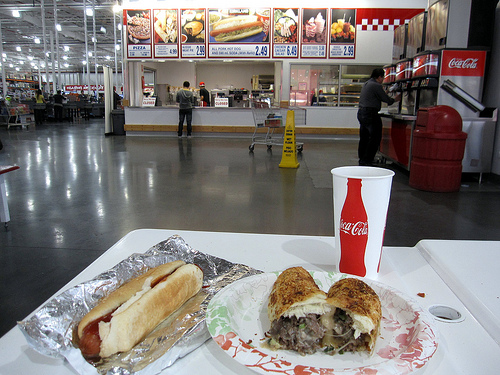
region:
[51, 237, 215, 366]
hot dog in tin foil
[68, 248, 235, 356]
hot dog with ketchup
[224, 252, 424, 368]
round plate with food on it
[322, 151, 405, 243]
cup next to plate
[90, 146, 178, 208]
floor next to the table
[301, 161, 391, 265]
white cup with red bottle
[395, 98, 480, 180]
red trash can on floor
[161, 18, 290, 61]
menu of food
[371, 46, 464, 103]
coke machine next to man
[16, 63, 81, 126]
people in the store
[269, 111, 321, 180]
the cone is yellow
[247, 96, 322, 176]
buggy behind the cone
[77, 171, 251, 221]
the floor is gray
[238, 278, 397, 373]
sandwich on the plate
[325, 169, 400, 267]
cup behind the plate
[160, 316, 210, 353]
the foil is aluminum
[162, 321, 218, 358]
the foil is silver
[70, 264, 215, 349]
hot dog in bun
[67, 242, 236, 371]
hot dog on foil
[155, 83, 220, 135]
man at the counter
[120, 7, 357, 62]
menu on wall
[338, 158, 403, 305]
paper cup is red and white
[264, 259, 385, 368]
meat inside two pieces of bread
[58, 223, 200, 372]
hot dog on aluminum foil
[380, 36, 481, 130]
red and white drink dispenser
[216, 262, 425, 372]
sandwich on red and white paper plate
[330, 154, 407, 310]
paper cup on white table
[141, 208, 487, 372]
table is white and plastic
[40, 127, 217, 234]
floor is reflective and grey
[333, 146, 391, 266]
red and white paper cup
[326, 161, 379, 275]
paper cup on white table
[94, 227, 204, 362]
hot dog in aluminum foil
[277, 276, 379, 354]
sandwich on paper plate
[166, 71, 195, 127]
person standing at food counter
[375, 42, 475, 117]
red and white soda fountain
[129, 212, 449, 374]
white plastic table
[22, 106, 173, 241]
grey reflective floor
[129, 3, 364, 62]
menu over service counter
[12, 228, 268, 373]
hot dog in bun on foil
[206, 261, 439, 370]
pastrami sandwich on floral plate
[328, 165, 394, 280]
paper Coca Cola cup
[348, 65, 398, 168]
man in black slacks and grey shirt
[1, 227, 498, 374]
white counter with food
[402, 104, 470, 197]
red trash receptacle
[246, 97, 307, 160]
shopping cart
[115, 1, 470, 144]
food counter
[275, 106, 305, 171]
yellow caution cone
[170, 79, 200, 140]
person in grey hoodie and black jeans